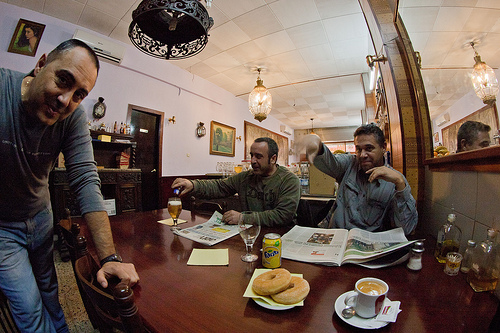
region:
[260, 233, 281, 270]
The yellow soda can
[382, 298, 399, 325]
The sugar on the coffee dish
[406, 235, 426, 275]
The shaker of white powder by the newspaper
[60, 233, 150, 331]
The empty chair by the table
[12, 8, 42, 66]
The painting behind the mans head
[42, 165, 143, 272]
The fire place being hidden by the table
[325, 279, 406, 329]
The cup of coffee on the table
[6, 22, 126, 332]
The man leaning against the table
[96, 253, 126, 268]
The watch on the mans wrist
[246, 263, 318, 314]
The bagels sitting on the table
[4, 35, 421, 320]
Three men in a room.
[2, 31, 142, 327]
A man standing by a table.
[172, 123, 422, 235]
Two men sitting at a table.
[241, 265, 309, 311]
A plate of donuts.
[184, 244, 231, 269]
A napkin on the table.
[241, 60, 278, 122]
A glass ceiling light.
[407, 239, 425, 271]
Salt on a table.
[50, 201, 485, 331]
A brown table.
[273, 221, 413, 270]
An open newspaper.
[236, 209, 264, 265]
An empty beer glass.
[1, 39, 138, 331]
a man in grey shirt standing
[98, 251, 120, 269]
watch on a man's wrist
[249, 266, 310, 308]
donuts on a plate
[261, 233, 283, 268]
a yellow can of fanta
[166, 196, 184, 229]
a glass of beer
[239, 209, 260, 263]
an empty glass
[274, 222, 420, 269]
newspaper on a table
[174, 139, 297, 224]
a man in green sitting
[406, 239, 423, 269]
a salt shaker on a table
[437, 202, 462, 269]
a glass bottle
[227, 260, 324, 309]
donuts on a plate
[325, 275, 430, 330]
a drink in a cup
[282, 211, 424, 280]
a newspaper unfolded on table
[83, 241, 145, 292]
a mans watch on wrist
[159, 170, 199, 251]
man poring a beer in a glass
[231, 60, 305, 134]
a light hangs from the ceiling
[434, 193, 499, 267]
a decanter on table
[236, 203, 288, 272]
a yellow can next to glass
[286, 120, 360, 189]
a man pointing to something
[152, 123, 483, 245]
2 men sit at a table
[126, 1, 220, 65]
The black iron chandiler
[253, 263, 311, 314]
The doughnuts on the table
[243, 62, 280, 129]
The lamp on the ceiling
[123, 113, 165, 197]
The door way in the back ground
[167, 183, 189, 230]
The glasses getting liquid poured into it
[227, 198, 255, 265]
The empty glass on the table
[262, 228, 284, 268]
The soda can on the table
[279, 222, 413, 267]
The newspaper on the table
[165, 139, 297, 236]
The man in the green shirt